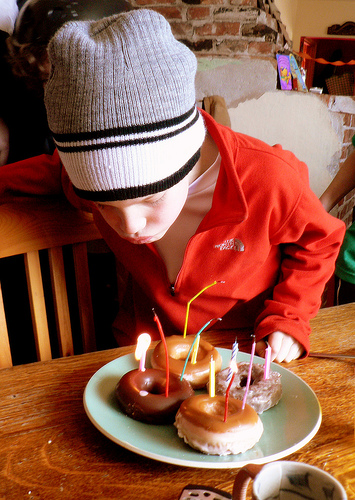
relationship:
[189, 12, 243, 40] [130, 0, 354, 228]
brick on wall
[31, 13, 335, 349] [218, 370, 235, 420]
child blowing out candle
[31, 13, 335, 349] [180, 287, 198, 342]
child blowing out candle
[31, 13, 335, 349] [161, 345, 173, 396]
child blowing out candle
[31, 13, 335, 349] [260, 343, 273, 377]
child blowing out candle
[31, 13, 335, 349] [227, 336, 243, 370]
child blowing out candle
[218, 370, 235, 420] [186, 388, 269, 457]
candle on doughnut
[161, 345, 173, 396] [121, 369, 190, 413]
candle on doughnut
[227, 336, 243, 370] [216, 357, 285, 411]
candle on doughnut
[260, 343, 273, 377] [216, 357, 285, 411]
candle on doughnut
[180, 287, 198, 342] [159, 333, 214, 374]
candle on doughnut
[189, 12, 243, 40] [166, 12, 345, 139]
brick in wall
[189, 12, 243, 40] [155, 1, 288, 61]
brick in wall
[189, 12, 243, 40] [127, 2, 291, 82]
brick in brick wall